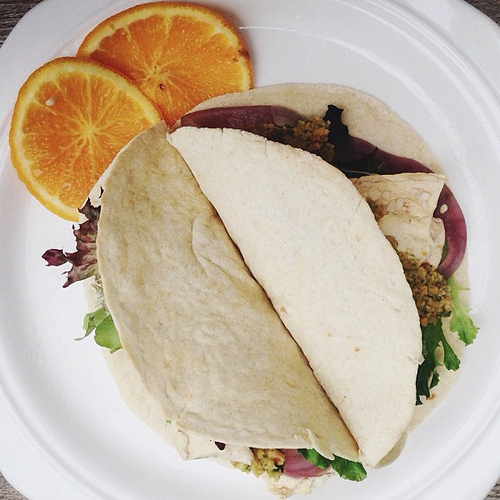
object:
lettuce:
[303, 450, 362, 481]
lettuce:
[413, 276, 477, 405]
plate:
[1, 11, 497, 498]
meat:
[393, 253, 459, 328]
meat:
[239, 438, 290, 483]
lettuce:
[80, 292, 138, 354]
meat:
[259, 111, 336, 163]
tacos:
[35, 81, 478, 487]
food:
[7, 0, 486, 497]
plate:
[19, 129, 498, 484]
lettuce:
[54, 210, 111, 284]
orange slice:
[81, 0, 254, 122]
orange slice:
[13, 63, 164, 219]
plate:
[249, 0, 421, 87]